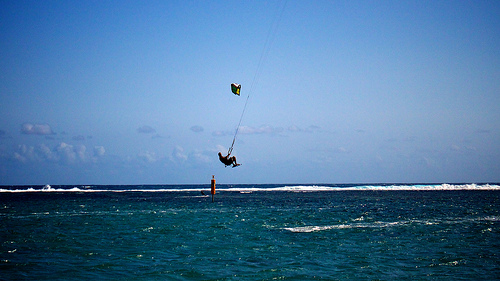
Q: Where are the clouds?
A: In the sky.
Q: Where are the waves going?
A: Towards the shore.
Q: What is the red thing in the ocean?
A: Buoy.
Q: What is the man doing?
A: Parasailing.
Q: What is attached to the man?
A: A Parashute.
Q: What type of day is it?
A: Sunny and clear.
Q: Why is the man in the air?
A: The Parachute lifted him up.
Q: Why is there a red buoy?
A: To mark the reefs.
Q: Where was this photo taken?
A: At the beach.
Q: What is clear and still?
A: Water.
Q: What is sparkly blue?
A: Water.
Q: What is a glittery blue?
A: Ocean.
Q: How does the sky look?
A: Mostly clear.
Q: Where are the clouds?
A: Lower part of sky.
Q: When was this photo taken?
A: During the day.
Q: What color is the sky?
A: Blue.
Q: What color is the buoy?
A: Red.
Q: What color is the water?
A: Dark blue.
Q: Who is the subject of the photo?
A: The person.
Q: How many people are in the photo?
A: One.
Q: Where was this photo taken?
A: At the beach.